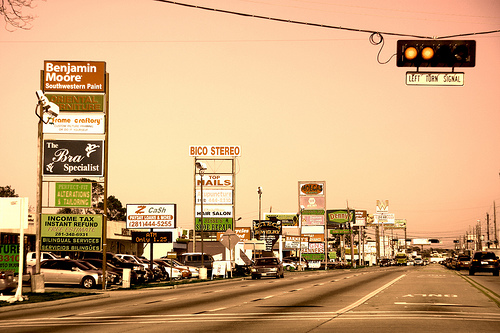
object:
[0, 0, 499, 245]
he sky is clear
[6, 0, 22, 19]
braches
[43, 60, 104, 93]
sign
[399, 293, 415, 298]
arrow in the street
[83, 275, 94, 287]
tire on the car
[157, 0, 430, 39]
electrical line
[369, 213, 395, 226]
white sign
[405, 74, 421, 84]
black words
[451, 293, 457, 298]
arrow on road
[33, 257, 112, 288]
tan car parked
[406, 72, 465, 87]
green and black sign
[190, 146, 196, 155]
red letters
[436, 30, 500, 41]
wire holding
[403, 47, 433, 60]
two orange lights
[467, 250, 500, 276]
dark car driving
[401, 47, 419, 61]
light on a pole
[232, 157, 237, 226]
sign on a pole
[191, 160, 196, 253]
pole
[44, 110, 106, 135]
sign on a pole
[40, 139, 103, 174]
sign on a pole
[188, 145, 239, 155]
sign on a pole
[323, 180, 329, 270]
sign on a pole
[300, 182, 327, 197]
sign on a pole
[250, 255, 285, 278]
car on a street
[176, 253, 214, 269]
car on a street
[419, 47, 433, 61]
signal light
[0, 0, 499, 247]
white clouds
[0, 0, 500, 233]
blue sky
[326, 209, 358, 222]
his is a sign